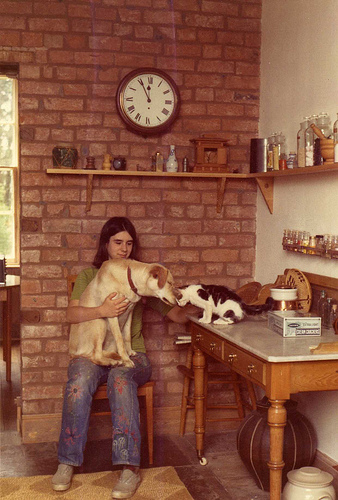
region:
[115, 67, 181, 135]
clock with brown frame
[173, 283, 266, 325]
a brown cat with black and white color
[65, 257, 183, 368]
a brown and white dog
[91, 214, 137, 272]
a lady with brown hair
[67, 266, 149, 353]
a green short sleeve shirt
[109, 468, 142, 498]
gray and white shoes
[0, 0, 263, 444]
a dark and light color brick wall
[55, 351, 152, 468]
blue jeans with red flowers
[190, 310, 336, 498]
white and brown table with wheels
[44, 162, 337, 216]
brown wooden shelf with supports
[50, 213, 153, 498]
a woman sitting in a chair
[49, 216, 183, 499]
a woman with a dog sitting in her lap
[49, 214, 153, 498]
a woman wearing a green shirt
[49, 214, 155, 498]
a woman wearing flowered jeans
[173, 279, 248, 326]
a black and white cat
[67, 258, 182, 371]
a light brown dog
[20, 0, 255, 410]
a brown brick wall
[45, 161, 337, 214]
a wooden corner wall shelf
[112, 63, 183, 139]
a brown and white hanging wall clock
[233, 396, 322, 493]
a large striped vase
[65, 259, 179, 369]
large tan dog that is in a girl's lap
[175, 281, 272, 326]
cat on a table that is hugging a dog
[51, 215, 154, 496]
girl with a green shirt is holding a large dog on her lap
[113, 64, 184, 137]
wall mounted clock with Roman numerals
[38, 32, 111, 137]
red bricks that compose the wall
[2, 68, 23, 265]
window looking outside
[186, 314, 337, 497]
a two drawer marble topped table with wheels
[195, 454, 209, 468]
white wheel on the table leg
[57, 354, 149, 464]
embroidered blue jeans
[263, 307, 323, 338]
blue and white box that is on the table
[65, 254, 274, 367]
A dog and cat.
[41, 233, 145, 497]
A girl sitting in chair.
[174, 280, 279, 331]
A cat sitting on table.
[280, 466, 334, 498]
A white jar under table.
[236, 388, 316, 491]
A brown jar under table.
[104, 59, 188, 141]
Clock on brick wall.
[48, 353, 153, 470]
Girl wearing jeans covered in flowers.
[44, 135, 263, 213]
Shelf on the wall.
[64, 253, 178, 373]
Dog in girl's lap.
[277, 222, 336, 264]
Bottles in rack on wall.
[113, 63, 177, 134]
round clock on wall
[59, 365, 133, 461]
flower designs on blue jeans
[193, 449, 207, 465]
wheel at bottom of table leg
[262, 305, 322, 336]
small box on table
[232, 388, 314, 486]
large pot on ground beneath table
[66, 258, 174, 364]
large dog on person's lap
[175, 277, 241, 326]
cat sitting on table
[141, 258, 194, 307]
dog and cat being affectionate towards each other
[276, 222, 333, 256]
row of small bottles on wall shelf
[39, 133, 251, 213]
items on shelf set in brick wall